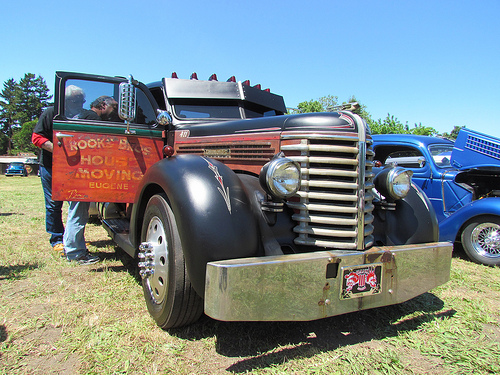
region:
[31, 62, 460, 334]
this vehicle is large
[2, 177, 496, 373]
the grass is worn down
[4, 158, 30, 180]
a truck in the background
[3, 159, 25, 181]
the truck is blue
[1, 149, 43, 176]
a building behind the truck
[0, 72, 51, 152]
a tree behind the building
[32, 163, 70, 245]
the man is wearing jeans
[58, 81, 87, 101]
his hair is white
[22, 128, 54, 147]
his shirt sleeve is red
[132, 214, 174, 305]
the wheel hub on the vehicle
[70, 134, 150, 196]
name of business on door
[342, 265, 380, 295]
front license plate with design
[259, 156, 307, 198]
right headlight on truck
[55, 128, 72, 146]
car door handle on truck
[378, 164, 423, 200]
left headlight on truck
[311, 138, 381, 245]
front grill on the truck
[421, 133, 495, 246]
blue car beside truck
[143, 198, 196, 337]
left car tire on truck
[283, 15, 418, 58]
beautiful blue sky in distance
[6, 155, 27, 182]
a blue truck parked by building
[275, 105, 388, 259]
The front grill of a truck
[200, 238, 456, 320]
The front bumper of a vehicle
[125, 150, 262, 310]
The front passenger-side fender.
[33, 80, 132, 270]
2 men looking into a vehicle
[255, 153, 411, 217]
The front headlights of a vehicle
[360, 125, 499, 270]
A blue vehicle with the hood up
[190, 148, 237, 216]
A design painted on a fender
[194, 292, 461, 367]
A shadow underneath the bumper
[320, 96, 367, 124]
A hood ornament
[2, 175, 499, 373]
A sparsely grass field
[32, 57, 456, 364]
a tractor on the grass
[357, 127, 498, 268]
a car behind the tractor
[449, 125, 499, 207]
the car hood is open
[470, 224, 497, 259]
the metal wheel of the car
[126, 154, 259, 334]
a giant tire of the tractor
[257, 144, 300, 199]
a light on the front of the tractor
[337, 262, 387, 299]
a design in front of the tractor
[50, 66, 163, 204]
a door is open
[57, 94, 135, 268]
a man looking into the truck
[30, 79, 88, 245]
a man standing behind him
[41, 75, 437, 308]
this is a truck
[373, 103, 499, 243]
this is a car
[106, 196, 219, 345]
a wheel of a car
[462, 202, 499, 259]
a wheel of a car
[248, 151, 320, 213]
this is a headlight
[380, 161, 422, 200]
this is a headlight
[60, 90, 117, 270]
this is a person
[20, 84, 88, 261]
this is a headlight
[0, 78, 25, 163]
this is a tree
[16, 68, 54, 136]
this is a tree